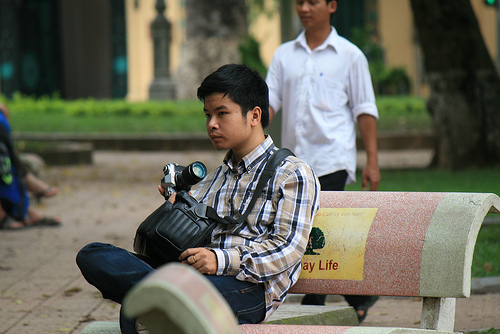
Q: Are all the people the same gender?
A: No, they are both male and female.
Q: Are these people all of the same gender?
A: No, they are both male and female.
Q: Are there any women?
A: Yes, there is a woman.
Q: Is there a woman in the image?
A: Yes, there is a woman.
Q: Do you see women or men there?
A: Yes, there is a woman.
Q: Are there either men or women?
A: Yes, there is a woman.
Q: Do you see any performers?
A: No, there are no performers.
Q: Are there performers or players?
A: No, there are no performers or players.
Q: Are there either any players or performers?
A: No, there are no performers or players.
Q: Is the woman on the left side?
A: Yes, the woman is on the left of the image.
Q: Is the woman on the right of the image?
A: No, the woman is on the left of the image.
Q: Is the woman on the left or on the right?
A: The woman is on the left of the image.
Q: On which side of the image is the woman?
A: The woman is on the left of the image.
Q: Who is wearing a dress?
A: The woman is wearing a dress.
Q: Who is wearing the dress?
A: The woman is wearing a dress.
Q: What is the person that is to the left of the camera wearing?
A: The woman is wearing a dress.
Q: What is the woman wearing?
A: The woman is wearing a dress.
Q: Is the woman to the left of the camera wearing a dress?
A: Yes, the woman is wearing a dress.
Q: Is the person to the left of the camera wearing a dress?
A: Yes, the woman is wearing a dress.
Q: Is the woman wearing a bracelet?
A: No, the woman is wearing a dress.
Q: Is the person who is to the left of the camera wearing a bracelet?
A: No, the woman is wearing a dress.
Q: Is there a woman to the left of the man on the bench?
A: Yes, there is a woman to the left of the man.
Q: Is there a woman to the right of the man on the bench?
A: No, the woman is to the left of the man.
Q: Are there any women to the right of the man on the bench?
A: No, the woman is to the left of the man.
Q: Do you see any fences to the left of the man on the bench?
A: No, there is a woman to the left of the man.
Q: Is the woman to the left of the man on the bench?
A: Yes, the woman is to the left of the man.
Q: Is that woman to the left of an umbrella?
A: No, the woman is to the left of the man.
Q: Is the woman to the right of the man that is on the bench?
A: No, the woman is to the left of the man.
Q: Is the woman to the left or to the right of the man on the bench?
A: The woman is to the left of the man.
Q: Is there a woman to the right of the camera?
A: No, the woman is to the left of the camera.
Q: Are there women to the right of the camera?
A: No, the woman is to the left of the camera.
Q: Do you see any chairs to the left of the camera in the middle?
A: No, there is a woman to the left of the camera.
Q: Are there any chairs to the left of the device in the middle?
A: No, there is a woman to the left of the camera.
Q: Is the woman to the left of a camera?
A: Yes, the woman is to the left of a camera.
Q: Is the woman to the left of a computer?
A: No, the woman is to the left of a camera.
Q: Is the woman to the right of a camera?
A: No, the woman is to the left of a camera.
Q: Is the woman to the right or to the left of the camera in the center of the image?
A: The woman is to the left of the camera.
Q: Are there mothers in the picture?
A: No, there are no mothers.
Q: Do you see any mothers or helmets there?
A: No, there are no mothers or helmets.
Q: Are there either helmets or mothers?
A: No, there are no mothers or helmets.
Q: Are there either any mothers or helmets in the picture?
A: No, there are no mothers or helmets.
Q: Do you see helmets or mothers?
A: No, there are no mothers or helmets.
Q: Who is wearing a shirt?
A: The man is wearing a shirt.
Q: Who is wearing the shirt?
A: The man is wearing a shirt.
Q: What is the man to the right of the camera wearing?
A: The man is wearing a shirt.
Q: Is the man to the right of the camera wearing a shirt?
A: Yes, the man is wearing a shirt.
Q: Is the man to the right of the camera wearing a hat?
A: No, the man is wearing a shirt.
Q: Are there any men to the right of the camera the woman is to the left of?
A: Yes, there is a man to the right of the camera.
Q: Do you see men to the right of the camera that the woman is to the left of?
A: Yes, there is a man to the right of the camera.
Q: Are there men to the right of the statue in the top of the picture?
A: Yes, there is a man to the right of the statue.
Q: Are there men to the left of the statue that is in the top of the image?
A: No, the man is to the right of the statue.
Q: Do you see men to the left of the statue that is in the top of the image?
A: No, the man is to the right of the statue.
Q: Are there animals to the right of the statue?
A: No, there is a man to the right of the statue.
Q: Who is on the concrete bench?
A: The man is on the bench.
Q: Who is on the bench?
A: The man is on the bench.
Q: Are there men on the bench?
A: Yes, there is a man on the bench.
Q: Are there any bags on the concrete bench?
A: No, there is a man on the bench.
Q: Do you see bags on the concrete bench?
A: No, there is a man on the bench.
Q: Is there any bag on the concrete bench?
A: No, there is a man on the bench.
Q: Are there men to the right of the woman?
A: Yes, there is a man to the right of the woman.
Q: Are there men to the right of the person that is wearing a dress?
A: Yes, there is a man to the right of the woman.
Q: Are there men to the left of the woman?
A: No, the man is to the right of the woman.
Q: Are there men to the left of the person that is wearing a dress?
A: No, the man is to the right of the woman.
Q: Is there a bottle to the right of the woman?
A: No, there is a man to the right of the woman.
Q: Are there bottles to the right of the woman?
A: No, there is a man to the right of the woman.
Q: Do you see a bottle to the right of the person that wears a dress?
A: No, there is a man to the right of the woman.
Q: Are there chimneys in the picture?
A: No, there are no chimneys.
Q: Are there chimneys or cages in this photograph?
A: No, there are no chimneys or cages.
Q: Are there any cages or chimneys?
A: No, there are no chimneys or cages.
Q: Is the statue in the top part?
A: Yes, the statue is in the top of the image.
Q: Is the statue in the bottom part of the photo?
A: No, the statue is in the top of the image.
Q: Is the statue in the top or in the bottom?
A: The statue is in the top of the image.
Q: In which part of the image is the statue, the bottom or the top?
A: The statue is in the top of the image.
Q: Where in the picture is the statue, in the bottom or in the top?
A: The statue is in the top of the image.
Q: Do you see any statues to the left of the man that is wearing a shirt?
A: Yes, there is a statue to the left of the man.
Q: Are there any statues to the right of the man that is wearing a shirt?
A: No, the statue is to the left of the man.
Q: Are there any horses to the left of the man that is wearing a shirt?
A: No, there is a statue to the left of the man.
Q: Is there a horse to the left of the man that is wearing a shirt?
A: No, there is a statue to the left of the man.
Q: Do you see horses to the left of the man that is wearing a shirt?
A: No, there is a statue to the left of the man.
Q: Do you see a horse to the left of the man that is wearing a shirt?
A: No, there is a statue to the left of the man.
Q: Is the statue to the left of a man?
A: Yes, the statue is to the left of a man.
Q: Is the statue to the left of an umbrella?
A: No, the statue is to the left of a man.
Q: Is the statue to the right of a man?
A: No, the statue is to the left of a man.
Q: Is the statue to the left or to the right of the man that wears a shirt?
A: The statue is to the left of the man.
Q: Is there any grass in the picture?
A: Yes, there is grass.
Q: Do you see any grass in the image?
A: Yes, there is grass.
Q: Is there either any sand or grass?
A: Yes, there is grass.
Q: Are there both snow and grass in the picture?
A: No, there is grass but no snow.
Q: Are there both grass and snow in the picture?
A: No, there is grass but no snow.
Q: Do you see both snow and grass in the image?
A: No, there is grass but no snow.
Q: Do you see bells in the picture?
A: No, there are no bells.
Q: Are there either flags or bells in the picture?
A: No, there are no bells or flags.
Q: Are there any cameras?
A: Yes, there is a camera.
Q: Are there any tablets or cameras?
A: Yes, there is a camera.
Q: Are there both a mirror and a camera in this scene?
A: No, there is a camera but no mirrors.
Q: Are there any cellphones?
A: No, there are no cellphones.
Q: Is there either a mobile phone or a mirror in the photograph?
A: No, there are no cell phones or mirrors.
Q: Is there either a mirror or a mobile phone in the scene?
A: No, there are no cell phones or mirrors.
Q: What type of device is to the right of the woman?
A: The device is a camera.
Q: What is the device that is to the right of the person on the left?
A: The device is a camera.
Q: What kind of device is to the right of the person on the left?
A: The device is a camera.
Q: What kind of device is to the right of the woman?
A: The device is a camera.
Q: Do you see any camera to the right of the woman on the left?
A: Yes, there is a camera to the right of the woman.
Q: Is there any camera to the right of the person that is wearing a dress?
A: Yes, there is a camera to the right of the woman.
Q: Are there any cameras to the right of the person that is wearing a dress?
A: Yes, there is a camera to the right of the woman.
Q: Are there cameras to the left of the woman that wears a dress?
A: No, the camera is to the right of the woman.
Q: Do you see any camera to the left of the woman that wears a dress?
A: No, the camera is to the right of the woman.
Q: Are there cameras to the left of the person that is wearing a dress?
A: No, the camera is to the right of the woman.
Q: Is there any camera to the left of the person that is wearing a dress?
A: No, the camera is to the right of the woman.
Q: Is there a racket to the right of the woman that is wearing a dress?
A: No, there is a camera to the right of the woman.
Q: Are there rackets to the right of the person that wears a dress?
A: No, there is a camera to the right of the woman.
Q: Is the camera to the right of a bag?
A: No, the camera is to the right of a woman.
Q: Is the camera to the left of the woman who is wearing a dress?
A: No, the camera is to the right of the woman.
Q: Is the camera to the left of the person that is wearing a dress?
A: No, the camera is to the right of the woman.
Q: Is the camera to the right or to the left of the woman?
A: The camera is to the right of the woman.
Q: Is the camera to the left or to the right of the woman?
A: The camera is to the right of the woman.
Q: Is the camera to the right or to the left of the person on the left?
A: The camera is to the right of the woman.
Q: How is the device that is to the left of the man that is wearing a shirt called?
A: The device is a camera.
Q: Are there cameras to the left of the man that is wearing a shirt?
A: Yes, there is a camera to the left of the man.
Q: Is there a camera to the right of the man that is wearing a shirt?
A: No, the camera is to the left of the man.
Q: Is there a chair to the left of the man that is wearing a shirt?
A: No, there is a camera to the left of the man.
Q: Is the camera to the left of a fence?
A: No, the camera is to the left of the man.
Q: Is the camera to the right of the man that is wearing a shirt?
A: No, the camera is to the left of the man.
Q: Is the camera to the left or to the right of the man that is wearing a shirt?
A: The camera is to the left of the man.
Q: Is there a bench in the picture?
A: Yes, there is a bench.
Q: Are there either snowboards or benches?
A: Yes, there is a bench.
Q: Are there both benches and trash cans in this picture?
A: No, there is a bench but no trash cans.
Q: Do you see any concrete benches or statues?
A: Yes, there is a concrete bench.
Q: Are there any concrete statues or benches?
A: Yes, there is a concrete bench.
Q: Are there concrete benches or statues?
A: Yes, there is a concrete bench.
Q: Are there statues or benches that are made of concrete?
A: Yes, the bench is made of concrete.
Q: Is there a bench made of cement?
A: Yes, there is a bench that is made of cement.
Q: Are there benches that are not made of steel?
A: Yes, there is a bench that is made of concrete.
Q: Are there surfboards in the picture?
A: No, there are no surfboards.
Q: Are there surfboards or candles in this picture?
A: No, there are no surfboards or candles.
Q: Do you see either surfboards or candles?
A: No, there are no surfboards or candles.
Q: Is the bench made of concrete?
A: Yes, the bench is made of concrete.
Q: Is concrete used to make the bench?
A: Yes, the bench is made of concrete.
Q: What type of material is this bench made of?
A: The bench is made of cement.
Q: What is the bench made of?
A: The bench is made of concrete.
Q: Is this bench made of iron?
A: No, the bench is made of concrete.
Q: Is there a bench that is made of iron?
A: No, there is a bench but it is made of concrete.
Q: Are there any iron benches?
A: No, there is a bench but it is made of concrete.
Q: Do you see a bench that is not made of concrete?
A: No, there is a bench but it is made of concrete.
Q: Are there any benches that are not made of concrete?
A: No, there is a bench but it is made of concrete.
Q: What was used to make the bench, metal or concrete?
A: The bench is made of concrete.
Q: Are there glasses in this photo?
A: No, there are no glasses.